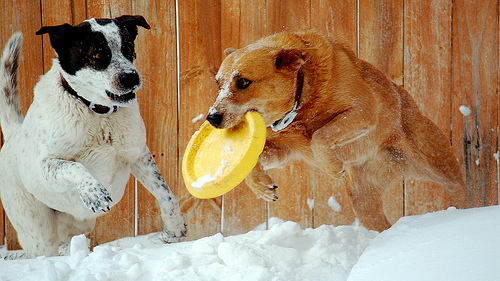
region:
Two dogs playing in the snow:
[4, 10, 462, 265]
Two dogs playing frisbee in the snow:
[10, 6, 480, 236]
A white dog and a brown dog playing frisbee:
[9, 7, 475, 270]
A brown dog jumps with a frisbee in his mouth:
[170, 15, 475, 262]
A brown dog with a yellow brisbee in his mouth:
[182, 6, 439, 235]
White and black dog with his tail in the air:
[4, 5, 185, 277]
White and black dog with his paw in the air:
[34, 8, 209, 245]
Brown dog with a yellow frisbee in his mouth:
[182, 29, 335, 134]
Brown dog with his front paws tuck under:
[196, 22, 378, 205]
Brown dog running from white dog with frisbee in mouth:
[3, 4, 473, 258]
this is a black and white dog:
[1, 13, 186, 256]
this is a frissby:
[180, 107, 267, 201]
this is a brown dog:
[205, 25, 477, 232]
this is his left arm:
[310, 105, 356, 185]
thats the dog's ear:
[268, 48, 304, 74]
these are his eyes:
[211, 75, 255, 90]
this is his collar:
[263, 70, 306, 133]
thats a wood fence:
[0, 0, 498, 250]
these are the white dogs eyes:
[88, 38, 136, 63]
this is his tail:
[0, 30, 26, 137]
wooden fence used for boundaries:
[150, 0, 499, 30]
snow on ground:
[158, 240, 498, 280]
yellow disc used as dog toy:
[181, 110, 266, 192]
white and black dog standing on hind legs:
[1, 14, 187, 253]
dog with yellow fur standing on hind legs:
[209, 26, 467, 229]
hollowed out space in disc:
[199, 137, 236, 159]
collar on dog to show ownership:
[51, 71, 124, 114]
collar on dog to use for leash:
[273, 65, 303, 130]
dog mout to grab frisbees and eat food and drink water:
[207, 95, 267, 133]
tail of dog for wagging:
[0, 30, 22, 128]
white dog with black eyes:
[3, 12, 184, 256]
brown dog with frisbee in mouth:
[174, 30, 474, 230]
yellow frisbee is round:
[174, 114, 267, 202]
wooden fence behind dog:
[0, 0, 498, 246]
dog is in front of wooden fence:
[1, 16, 181, 253]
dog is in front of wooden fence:
[179, 32, 475, 233]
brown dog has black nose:
[210, 28, 478, 233]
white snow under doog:
[4, 203, 497, 278]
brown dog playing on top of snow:
[184, 31, 467, 237]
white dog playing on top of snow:
[0, 15, 190, 261]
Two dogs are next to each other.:
[0, 0, 496, 276]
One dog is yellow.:
[180, 20, 470, 240]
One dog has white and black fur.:
[0, 5, 185, 250]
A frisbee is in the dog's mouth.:
[175, 35, 300, 200]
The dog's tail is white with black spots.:
[0, 25, 25, 135]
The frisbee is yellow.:
[176, 105, 261, 195]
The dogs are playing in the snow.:
[3, 13, 498, 278]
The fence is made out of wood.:
[180, 1, 498, 31]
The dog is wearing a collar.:
[268, 65, 310, 144]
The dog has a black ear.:
[33, 21, 70, 48]